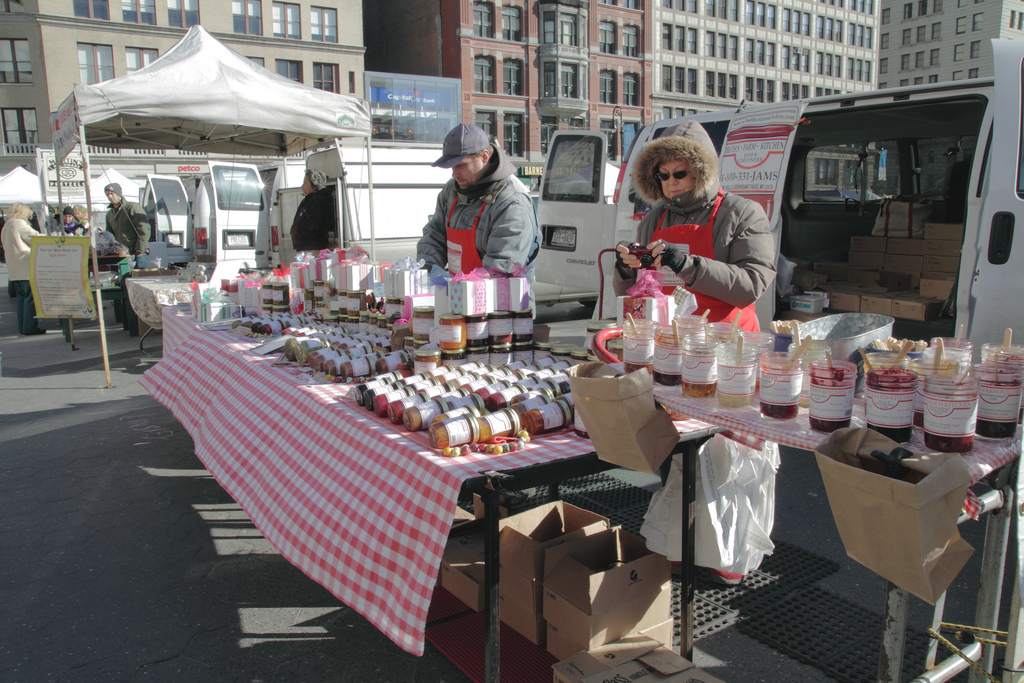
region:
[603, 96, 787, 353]
the woman has a gray coat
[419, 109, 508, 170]
the cap is blue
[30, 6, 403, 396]
a canopy on the street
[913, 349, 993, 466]
a cup of food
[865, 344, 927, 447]
a cup of food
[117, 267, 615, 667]
the table is covered with a tablecloth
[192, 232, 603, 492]
food on a table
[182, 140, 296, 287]
the door is open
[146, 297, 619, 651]
a red checkered table cloth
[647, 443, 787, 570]
hanging plastic white bags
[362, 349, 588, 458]
jars of jam on a table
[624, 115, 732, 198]
a fur lined hood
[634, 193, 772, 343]
a red apron over a coat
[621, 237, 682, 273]
a cell phone in a woman's hands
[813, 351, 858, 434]
a large glass jar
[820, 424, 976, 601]
a trash bucket attached to a table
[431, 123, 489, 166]
a black baseball cap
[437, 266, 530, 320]
a pink and white box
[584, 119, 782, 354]
a woman holding a camera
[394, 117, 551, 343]
a man standing behind the table of jarred goods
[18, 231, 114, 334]
a yellow, white and black sign on a pole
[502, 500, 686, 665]
cardboard boxes under the table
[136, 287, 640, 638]
a red and white checkered table cloth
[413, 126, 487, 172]
a gray cap on his head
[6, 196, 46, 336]
a woman in a white coat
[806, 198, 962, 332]
boxes inside the van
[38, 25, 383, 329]
a white tent over the table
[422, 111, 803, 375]
two people in red aprons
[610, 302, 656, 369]
jar of jam at a cold market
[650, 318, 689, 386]
jar of jam at a cold market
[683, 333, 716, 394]
jar of jam at a cold market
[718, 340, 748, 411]
jar of jam at a cold market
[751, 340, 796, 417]
jar of jam at a cold market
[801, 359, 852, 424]
jar of jam at a cold market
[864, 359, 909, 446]
jar of jam at a cold market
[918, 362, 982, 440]
jar of jam at a cold market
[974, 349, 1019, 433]
jar of jam at a cold market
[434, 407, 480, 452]
jar of jam at a cold market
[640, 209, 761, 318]
woman wearing apron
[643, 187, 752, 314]
apron is red in color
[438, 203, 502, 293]
man is wearing apron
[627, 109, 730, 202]
woman is wearing a furry hood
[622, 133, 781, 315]
woman is wearing a jacket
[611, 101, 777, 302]
jacket is grey in color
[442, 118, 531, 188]
man is wearing a hat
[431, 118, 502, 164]
hat is grey in color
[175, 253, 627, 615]
table has a cloth on it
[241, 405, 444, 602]
table cloth is checkered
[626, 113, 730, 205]
hood is lined in fur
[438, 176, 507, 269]
man is wearing an apron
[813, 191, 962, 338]
boxes in the van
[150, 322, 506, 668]
tablecloth is red and white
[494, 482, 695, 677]
boxes under the table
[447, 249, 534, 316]
ribbons on the boxes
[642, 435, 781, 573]
stack of plastic shopping bags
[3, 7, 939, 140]
a row of buildings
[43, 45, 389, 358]
a large white tent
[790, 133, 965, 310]
the door on the van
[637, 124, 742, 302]
a person in a red apron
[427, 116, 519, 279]
a person with a grey cap on